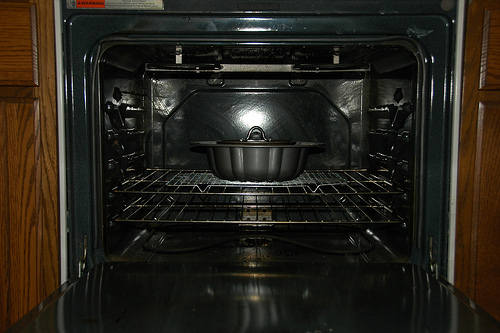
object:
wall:
[198, 92, 327, 119]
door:
[0, 90, 59, 328]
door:
[9, 255, 497, 331]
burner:
[152, 209, 343, 271]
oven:
[67, 2, 457, 294]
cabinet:
[449, 0, 496, 321]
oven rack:
[111, 167, 402, 197]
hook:
[197, 47, 309, 70]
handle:
[239, 124, 274, 143]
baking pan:
[191, 127, 323, 182]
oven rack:
[112, 195, 399, 224]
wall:
[93, 47, 151, 262]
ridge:
[101, 101, 144, 112]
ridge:
[108, 128, 147, 140]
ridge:
[108, 149, 147, 169]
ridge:
[112, 169, 146, 197]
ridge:
[110, 193, 145, 230]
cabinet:
[1, 1, 57, 331]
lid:
[215, 124, 298, 145]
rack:
[164, 165, 348, 193]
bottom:
[109, 202, 415, 264]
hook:
[424, 235, 440, 279]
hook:
[76, 229, 92, 279]